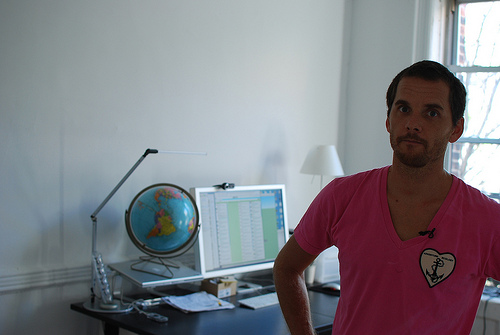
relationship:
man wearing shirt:
[272, 60, 499, 335] [294, 166, 499, 332]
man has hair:
[272, 60, 499, 332] [383, 58, 464, 172]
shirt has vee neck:
[294, 166, 499, 332] [376, 163, 463, 245]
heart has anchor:
[417, 250, 456, 289] [424, 257, 444, 284]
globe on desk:
[124, 185, 197, 258] [48, 295, 323, 333]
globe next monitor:
[117, 185, 204, 257] [187, 181, 294, 277]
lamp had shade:
[298, 141, 348, 193] [301, 141, 344, 177]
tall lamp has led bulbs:
[80, 140, 159, 311] [147, 147, 157, 155]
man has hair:
[272, 60, 499, 332] [373, 59, 466, 118]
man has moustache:
[272, 60, 499, 335] [380, 127, 436, 153]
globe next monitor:
[124, 185, 197, 258] [193, 176, 293, 297]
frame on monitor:
[184, 176, 303, 280] [189, 176, 298, 291]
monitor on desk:
[186, 182, 288, 293] [70, 278, 338, 333]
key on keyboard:
[266, 293, 273, 303] [234, 290, 292, 309]